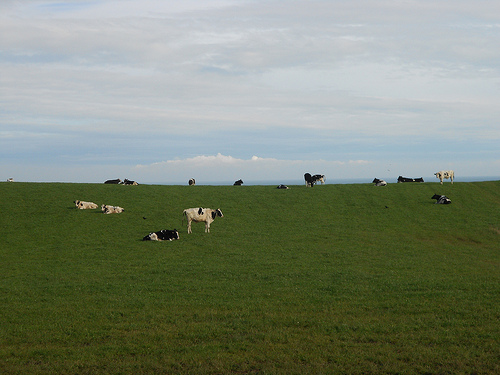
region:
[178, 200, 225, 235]
Cow standing in grass covered field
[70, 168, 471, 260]
Cows in grass covered field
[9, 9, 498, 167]
Grey clouds in sky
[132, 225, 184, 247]
Black and white cow lying in the grass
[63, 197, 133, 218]
Two cows lying in the grass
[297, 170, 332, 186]
Two cows grazing the field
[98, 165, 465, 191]
Cows on top of hill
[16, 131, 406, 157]
Blue patch of sky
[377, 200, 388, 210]
Black bird in field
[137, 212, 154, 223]
Black bird in field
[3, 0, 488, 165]
The sky is cloudy.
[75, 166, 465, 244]
The cows are grazing.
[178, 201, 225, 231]
The cow is standing.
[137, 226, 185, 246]
The cow is sitting.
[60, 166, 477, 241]
The cows are on the grass.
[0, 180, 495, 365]
The grass is green.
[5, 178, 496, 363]
The grass is lush.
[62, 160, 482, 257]
Many cows are together.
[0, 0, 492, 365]
The sun is shining.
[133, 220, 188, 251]
The cow is black.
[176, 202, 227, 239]
white and black cow on a pasture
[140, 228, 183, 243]
black with white spots laying on a pasture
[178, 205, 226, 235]
white cow with black spots standing on a pasture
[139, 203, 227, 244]
two cows on a pasture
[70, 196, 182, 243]
three cows laying down on a pasture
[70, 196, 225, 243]
four cows on a pasture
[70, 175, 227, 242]
seven cows on a pasture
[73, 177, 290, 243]
nine cows on a pasture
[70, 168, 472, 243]
lots of cows on a pasture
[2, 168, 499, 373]
many cows on a large green pasture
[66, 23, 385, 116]
Sky is white color.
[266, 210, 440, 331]
Grass is green color.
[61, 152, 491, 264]
Cows are in grass.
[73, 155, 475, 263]
Cows are black and white color.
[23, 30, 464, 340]
Day time picture.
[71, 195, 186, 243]
Cow are sitting in the grass.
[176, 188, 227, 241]
Cow is standing in grass.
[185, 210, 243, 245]
Cow has four legs.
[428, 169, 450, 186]
Cow has two ears.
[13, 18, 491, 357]
Picture is taken in outdoor.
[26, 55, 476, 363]
The cows are in a field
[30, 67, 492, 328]
The cows are eating the grass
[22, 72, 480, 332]
The cows are standing on the grass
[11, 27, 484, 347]
Some cows are laying in a field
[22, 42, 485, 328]
The cows are very relaxed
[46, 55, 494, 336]
The cows are on a farm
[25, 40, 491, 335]
The cows are looking for food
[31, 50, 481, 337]
The cows are watching for danger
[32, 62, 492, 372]
The cows are owned by a farmer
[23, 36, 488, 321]
Some cows are owned by a dairy farm